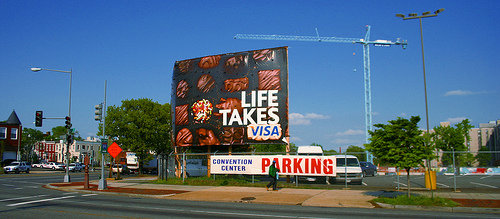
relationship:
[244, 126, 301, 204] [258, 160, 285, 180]
man in jacket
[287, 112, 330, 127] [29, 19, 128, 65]
clouds in sky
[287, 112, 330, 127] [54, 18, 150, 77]
clouds in sky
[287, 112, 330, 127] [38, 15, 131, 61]
clouds in sky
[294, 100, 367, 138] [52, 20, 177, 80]
clouds in sky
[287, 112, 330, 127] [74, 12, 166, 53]
clouds in sky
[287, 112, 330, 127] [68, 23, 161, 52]
clouds in sky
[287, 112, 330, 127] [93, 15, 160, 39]
clouds in sky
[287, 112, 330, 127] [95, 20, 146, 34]
clouds in sky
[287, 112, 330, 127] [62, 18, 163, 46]
clouds in sky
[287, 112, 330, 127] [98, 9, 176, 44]
clouds in sky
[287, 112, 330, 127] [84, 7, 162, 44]
clouds in sky